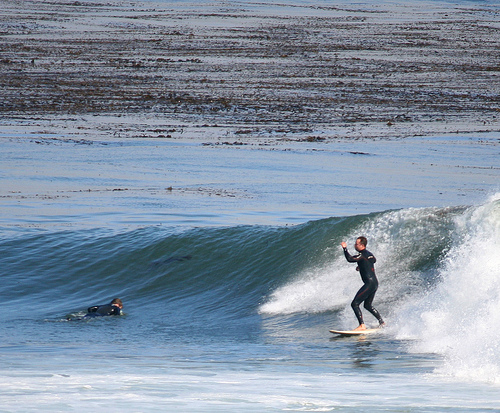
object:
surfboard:
[328, 327, 388, 337]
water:
[0, 3, 497, 409]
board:
[304, 289, 422, 326]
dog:
[73, 297, 121, 321]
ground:
[430, 148, 477, 188]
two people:
[57, 234, 384, 331]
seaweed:
[3, 10, 497, 145]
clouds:
[156, 8, 426, 30]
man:
[323, 228, 395, 333]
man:
[79, 298, 124, 321]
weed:
[71, 185, 233, 196]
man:
[341, 234, 388, 331]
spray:
[283, 210, 498, 386]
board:
[328, 327, 382, 335]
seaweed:
[144, 250, 194, 265]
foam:
[437, 236, 497, 383]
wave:
[9, 190, 495, 342]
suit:
[342, 246, 384, 326]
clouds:
[29, 19, 70, 91]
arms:
[343, 247, 360, 263]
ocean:
[2, 1, 484, 411]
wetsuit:
[80, 304, 122, 318]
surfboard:
[120, 309, 125, 315]